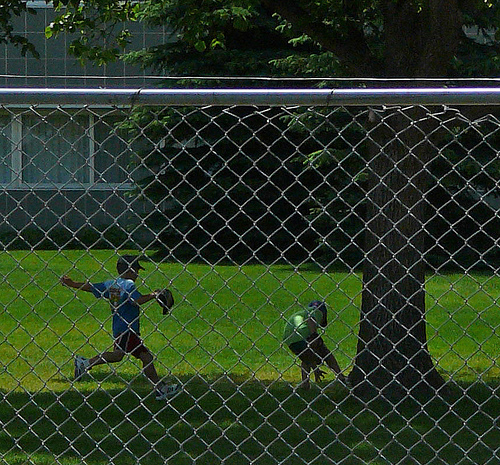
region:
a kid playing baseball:
[78, 243, 196, 386]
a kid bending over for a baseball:
[263, 276, 385, 463]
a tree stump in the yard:
[373, 184, 477, 410]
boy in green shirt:
[272, 292, 390, 422]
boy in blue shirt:
[61, 235, 237, 421]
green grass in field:
[203, 265, 290, 368]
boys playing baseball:
[40, 215, 435, 462]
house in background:
[30, 30, 230, 292]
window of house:
[36, 72, 194, 220]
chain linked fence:
[47, 158, 457, 435]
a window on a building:
[93, 112, 146, 180]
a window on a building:
[19, 112, 94, 186]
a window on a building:
[0, 113, 10, 181]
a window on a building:
[25, 7, 45, 28]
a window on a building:
[27, 34, 44, 55]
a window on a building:
[28, 58, 43, 79]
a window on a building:
[46, 30, 63, 55]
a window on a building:
[44, 57, 64, 74]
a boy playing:
[57, 253, 194, 410]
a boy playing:
[260, 275, 362, 403]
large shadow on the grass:
[105, 345, 402, 435]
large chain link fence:
[95, 80, 476, 330]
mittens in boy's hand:
[150, 280, 205, 335]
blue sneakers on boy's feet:
[60, 345, 115, 380]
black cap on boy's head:
[107, 245, 150, 271]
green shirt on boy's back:
[255, 285, 342, 349]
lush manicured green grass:
[210, 275, 275, 332]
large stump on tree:
[344, 280, 464, 400]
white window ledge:
[18, 164, 150, 204]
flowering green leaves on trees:
[125, 50, 497, 235]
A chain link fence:
[20, 212, 485, 454]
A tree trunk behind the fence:
[356, 125, 446, 390]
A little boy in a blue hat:
[275, 290, 347, 386]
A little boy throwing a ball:
[50, 246, 186, 396]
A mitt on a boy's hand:
[142, 276, 182, 316]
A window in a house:
[10, 96, 170, 187]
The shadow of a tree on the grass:
[62, 374, 357, 456]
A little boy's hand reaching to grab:
[302, 360, 332, 388]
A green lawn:
[174, 272, 300, 312]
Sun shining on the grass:
[14, 259, 68, 370]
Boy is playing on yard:
[47, 241, 191, 411]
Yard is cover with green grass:
[5, 250, 497, 464]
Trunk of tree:
[345, 130, 480, 402]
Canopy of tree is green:
[12, 1, 494, 129]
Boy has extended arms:
[37, 247, 199, 408]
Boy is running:
[47, 251, 207, 406]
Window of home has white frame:
[4, 95, 164, 202]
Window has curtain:
[7, 105, 144, 199]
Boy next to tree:
[271, 295, 356, 402]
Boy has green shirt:
[277, 288, 354, 395]